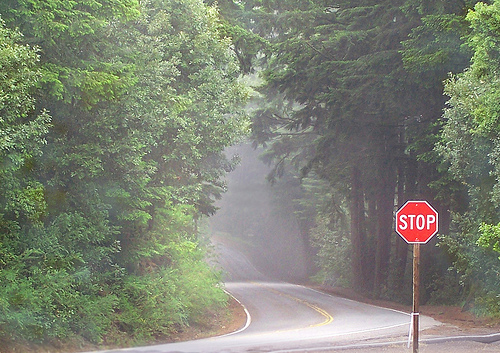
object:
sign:
[392, 200, 440, 245]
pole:
[409, 242, 420, 353]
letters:
[398, 214, 409, 231]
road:
[71, 240, 439, 353]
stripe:
[245, 277, 335, 326]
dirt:
[166, 287, 248, 343]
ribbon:
[405, 312, 421, 350]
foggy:
[182, 231, 302, 286]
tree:
[249, 2, 472, 298]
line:
[216, 288, 253, 337]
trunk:
[372, 147, 393, 299]